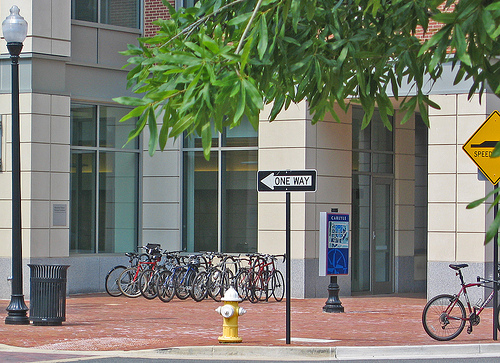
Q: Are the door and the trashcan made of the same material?
A: No, the door is made of glass and the trashcan is made of metal.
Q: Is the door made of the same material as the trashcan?
A: No, the door is made of glass and the trashcan is made of metal.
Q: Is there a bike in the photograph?
A: Yes, there is a bike.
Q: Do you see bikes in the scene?
A: Yes, there is a bike.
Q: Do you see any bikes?
A: Yes, there is a bike.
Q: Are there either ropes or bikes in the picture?
A: Yes, there is a bike.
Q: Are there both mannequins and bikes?
A: No, there is a bike but no mannequins.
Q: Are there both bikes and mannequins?
A: No, there is a bike but no mannequins.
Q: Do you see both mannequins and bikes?
A: No, there is a bike but no mannequins.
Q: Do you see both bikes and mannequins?
A: No, there is a bike but no mannequins.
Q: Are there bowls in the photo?
A: No, there are no bowls.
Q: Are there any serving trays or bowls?
A: No, there are no bowls or serving trays.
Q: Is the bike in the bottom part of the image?
A: Yes, the bike is in the bottom of the image.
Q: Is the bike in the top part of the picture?
A: No, the bike is in the bottom of the image.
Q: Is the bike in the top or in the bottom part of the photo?
A: The bike is in the bottom of the image.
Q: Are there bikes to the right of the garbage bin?
A: Yes, there is a bike to the right of the garbage bin.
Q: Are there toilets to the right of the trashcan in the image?
A: No, there is a bike to the right of the trashcan.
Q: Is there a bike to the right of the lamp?
A: Yes, there is a bike to the right of the lamp.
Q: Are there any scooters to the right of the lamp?
A: No, there is a bike to the right of the lamp.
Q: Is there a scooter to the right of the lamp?
A: No, there is a bike to the right of the lamp.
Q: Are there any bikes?
A: Yes, there is a bike.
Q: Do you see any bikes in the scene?
A: Yes, there is a bike.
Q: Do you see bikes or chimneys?
A: Yes, there is a bike.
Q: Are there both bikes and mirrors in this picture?
A: No, there is a bike but no mirrors.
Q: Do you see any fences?
A: No, there are no fences.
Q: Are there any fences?
A: No, there are no fences.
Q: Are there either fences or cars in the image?
A: No, there are no fences or cars.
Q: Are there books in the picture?
A: No, there are no books.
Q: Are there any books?
A: No, there are no books.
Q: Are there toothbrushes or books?
A: No, there are no books or toothbrushes.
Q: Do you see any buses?
A: No, there are no buses.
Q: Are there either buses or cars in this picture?
A: No, there are no buses or cars.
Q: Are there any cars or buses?
A: No, there are no buses or cars.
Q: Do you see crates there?
A: No, there are no crates.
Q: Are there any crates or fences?
A: No, there are no crates or fences.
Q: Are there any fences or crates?
A: No, there are no crates or fences.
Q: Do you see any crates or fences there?
A: No, there are no crates or fences.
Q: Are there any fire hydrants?
A: Yes, there is a fire hydrant.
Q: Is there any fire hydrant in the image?
A: Yes, there is a fire hydrant.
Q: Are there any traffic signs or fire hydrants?
A: Yes, there is a fire hydrant.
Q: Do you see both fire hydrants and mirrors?
A: No, there is a fire hydrant but no mirrors.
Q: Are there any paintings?
A: No, there are no paintings.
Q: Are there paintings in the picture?
A: No, there are no paintings.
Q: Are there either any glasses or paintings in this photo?
A: No, there are no paintings or glasses.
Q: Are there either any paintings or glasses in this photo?
A: No, there are no paintings or glasses.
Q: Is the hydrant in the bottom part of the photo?
A: Yes, the hydrant is in the bottom of the image.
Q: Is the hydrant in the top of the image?
A: No, the hydrant is in the bottom of the image.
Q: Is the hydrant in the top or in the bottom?
A: The hydrant is in the bottom of the image.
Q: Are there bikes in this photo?
A: Yes, there is a bike.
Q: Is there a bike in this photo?
A: Yes, there is a bike.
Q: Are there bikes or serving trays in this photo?
A: Yes, there is a bike.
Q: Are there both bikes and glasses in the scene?
A: No, there is a bike but no glasses.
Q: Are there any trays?
A: No, there are no trays.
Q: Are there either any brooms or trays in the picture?
A: No, there are no trays or brooms.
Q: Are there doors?
A: Yes, there is a door.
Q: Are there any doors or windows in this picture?
A: Yes, there is a door.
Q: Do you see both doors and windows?
A: Yes, there are both a door and a window.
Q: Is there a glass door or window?
A: Yes, there is a glass door.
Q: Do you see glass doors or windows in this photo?
A: Yes, there is a glass door.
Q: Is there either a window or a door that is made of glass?
A: Yes, the door is made of glass.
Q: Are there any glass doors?
A: Yes, there is a door that is made of glass.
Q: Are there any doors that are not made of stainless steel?
A: Yes, there is a door that is made of glass.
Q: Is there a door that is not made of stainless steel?
A: Yes, there is a door that is made of glass.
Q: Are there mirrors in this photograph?
A: No, there are no mirrors.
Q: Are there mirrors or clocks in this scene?
A: No, there are no mirrors or clocks.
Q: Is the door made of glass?
A: Yes, the door is made of glass.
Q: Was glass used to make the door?
A: Yes, the door is made of glass.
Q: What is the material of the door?
A: The door is made of glass.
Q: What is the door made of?
A: The door is made of glass.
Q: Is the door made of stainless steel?
A: No, the door is made of glass.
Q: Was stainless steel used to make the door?
A: No, the door is made of glass.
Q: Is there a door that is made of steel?
A: No, there is a door but it is made of glass.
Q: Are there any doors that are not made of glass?
A: No, there is a door but it is made of glass.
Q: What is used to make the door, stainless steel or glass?
A: The door is made of glass.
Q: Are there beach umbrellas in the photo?
A: No, there are no beach umbrellas.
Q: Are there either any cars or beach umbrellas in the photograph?
A: No, there are no beach umbrellas or cars.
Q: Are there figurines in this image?
A: No, there are no figurines.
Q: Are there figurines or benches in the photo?
A: No, there are no figurines or benches.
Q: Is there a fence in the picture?
A: No, there are no fences.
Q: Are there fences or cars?
A: No, there are no fences or cars.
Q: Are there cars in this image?
A: No, there are no cars.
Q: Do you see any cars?
A: No, there are no cars.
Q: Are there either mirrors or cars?
A: No, there are no cars or mirrors.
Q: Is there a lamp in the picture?
A: Yes, there is a lamp.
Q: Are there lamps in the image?
A: Yes, there is a lamp.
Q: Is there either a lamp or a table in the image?
A: Yes, there is a lamp.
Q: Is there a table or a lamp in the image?
A: Yes, there is a lamp.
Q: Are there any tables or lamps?
A: Yes, there is a lamp.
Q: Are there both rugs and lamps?
A: No, there is a lamp but no rugs.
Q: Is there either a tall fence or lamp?
A: Yes, there is a tall lamp.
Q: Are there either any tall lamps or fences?
A: Yes, there is a tall lamp.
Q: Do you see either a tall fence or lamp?
A: Yes, there is a tall lamp.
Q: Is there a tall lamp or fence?
A: Yes, there is a tall lamp.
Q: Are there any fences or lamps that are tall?
A: Yes, the lamp is tall.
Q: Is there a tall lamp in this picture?
A: Yes, there is a tall lamp.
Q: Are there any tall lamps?
A: Yes, there is a tall lamp.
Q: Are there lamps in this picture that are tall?
A: Yes, there is a lamp that is tall.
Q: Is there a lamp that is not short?
A: Yes, there is a tall lamp.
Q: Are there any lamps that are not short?
A: Yes, there is a tall lamp.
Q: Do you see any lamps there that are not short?
A: Yes, there is a tall lamp.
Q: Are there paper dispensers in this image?
A: No, there are no paper dispensers.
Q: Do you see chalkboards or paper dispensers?
A: No, there are no paper dispensers or chalkboards.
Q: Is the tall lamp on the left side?
A: Yes, the lamp is on the left of the image.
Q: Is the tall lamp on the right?
A: No, the lamp is on the left of the image.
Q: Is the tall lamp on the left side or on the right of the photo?
A: The lamp is on the left of the image.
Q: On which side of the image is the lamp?
A: The lamp is on the left of the image.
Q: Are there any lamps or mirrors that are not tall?
A: No, there is a lamp but it is tall.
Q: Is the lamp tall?
A: Yes, the lamp is tall.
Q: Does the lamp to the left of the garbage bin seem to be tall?
A: Yes, the lamp is tall.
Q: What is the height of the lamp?
A: The lamp is tall.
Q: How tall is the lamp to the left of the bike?
A: The lamp is tall.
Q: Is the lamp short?
A: No, the lamp is tall.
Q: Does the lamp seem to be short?
A: No, the lamp is tall.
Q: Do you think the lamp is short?
A: No, the lamp is tall.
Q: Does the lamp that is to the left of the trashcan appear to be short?
A: No, the lamp is tall.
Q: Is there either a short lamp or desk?
A: No, there is a lamp but it is tall.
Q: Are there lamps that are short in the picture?
A: No, there is a lamp but it is tall.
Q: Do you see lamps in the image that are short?
A: No, there is a lamp but it is tall.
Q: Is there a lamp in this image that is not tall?
A: No, there is a lamp but it is tall.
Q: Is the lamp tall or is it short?
A: The lamp is tall.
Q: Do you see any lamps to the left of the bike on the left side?
A: Yes, there is a lamp to the left of the bike.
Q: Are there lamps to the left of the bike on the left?
A: Yes, there is a lamp to the left of the bike.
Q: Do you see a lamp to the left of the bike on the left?
A: Yes, there is a lamp to the left of the bike.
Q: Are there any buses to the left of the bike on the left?
A: No, there is a lamp to the left of the bike.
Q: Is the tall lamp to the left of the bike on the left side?
A: Yes, the lamp is to the left of the bike.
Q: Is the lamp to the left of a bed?
A: No, the lamp is to the left of the bike.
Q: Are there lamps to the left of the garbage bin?
A: Yes, there is a lamp to the left of the garbage bin.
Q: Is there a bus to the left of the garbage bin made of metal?
A: No, there is a lamp to the left of the garbage can.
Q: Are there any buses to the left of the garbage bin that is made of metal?
A: No, there is a lamp to the left of the garbage can.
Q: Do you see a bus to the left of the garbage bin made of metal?
A: No, there is a lamp to the left of the garbage can.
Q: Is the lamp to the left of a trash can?
A: Yes, the lamp is to the left of a trash can.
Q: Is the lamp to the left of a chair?
A: No, the lamp is to the left of a trash can.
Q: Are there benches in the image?
A: No, there are no benches.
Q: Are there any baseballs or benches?
A: No, there are no benches or baseballs.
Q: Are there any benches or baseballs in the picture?
A: No, there are no benches or baseballs.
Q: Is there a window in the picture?
A: Yes, there are windows.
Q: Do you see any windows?
A: Yes, there are windows.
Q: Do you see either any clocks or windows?
A: Yes, there are windows.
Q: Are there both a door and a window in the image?
A: Yes, there are both a window and a door.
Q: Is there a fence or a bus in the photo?
A: No, there are no fences or buses.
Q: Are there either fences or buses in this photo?
A: No, there are no fences or buses.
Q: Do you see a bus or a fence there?
A: No, there are no fences or buses.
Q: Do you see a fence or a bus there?
A: No, there are no fences or buses.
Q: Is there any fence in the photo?
A: No, there are no fences.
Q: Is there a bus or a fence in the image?
A: No, there are no fences or buses.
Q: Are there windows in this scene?
A: Yes, there are windows.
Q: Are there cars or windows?
A: Yes, there are windows.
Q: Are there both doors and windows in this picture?
A: Yes, there are both windows and doors.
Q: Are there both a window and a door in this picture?
A: Yes, there are both a window and a door.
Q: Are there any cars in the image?
A: No, there are no cars.